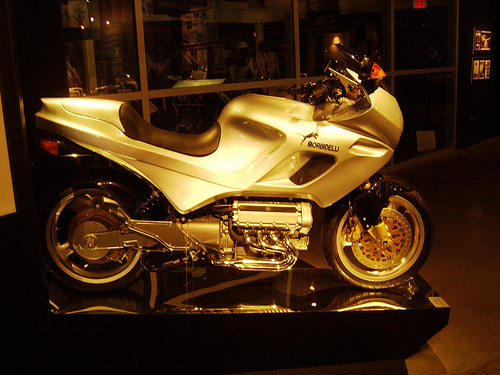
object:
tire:
[320, 175, 437, 289]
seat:
[119, 102, 221, 156]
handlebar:
[308, 83, 329, 105]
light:
[40, 140, 59, 156]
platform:
[40, 261, 451, 364]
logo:
[307, 140, 340, 153]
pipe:
[215, 259, 284, 273]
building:
[1, 2, 498, 375]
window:
[139, 1, 296, 94]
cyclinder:
[238, 225, 254, 232]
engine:
[230, 200, 313, 236]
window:
[336, 43, 392, 95]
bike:
[32, 34, 436, 295]